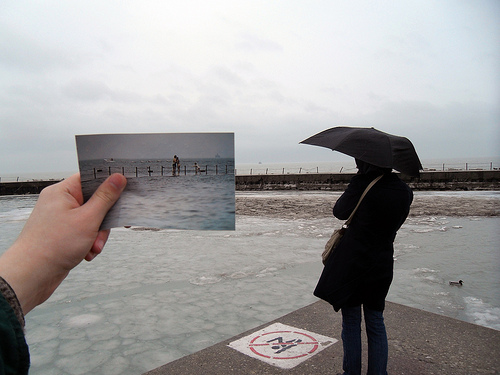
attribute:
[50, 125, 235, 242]
photo — held upward, matched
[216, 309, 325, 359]
sign — no swimming, warning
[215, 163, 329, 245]
water — murky, icy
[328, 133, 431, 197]
umbrella — black, open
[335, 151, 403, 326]
coat — black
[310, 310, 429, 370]
jeans — blue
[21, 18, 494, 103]
sky — opened, cloudy, overcast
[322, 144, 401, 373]
woman — standing, wearing black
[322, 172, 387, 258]
sling bag — light-colored, brown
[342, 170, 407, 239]
shirt — long-sleeve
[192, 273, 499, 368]
ground — brown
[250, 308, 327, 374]
circle — red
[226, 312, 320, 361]
square — white